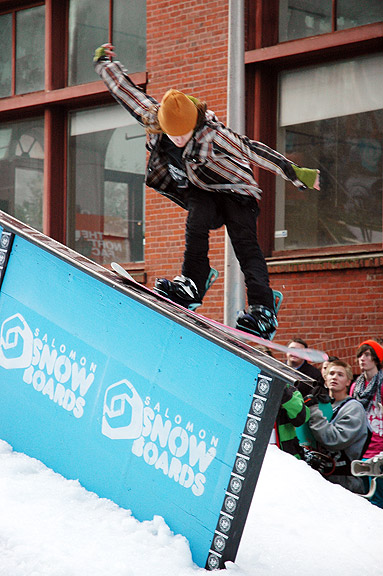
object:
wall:
[144, 0, 232, 330]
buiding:
[0, 0, 383, 381]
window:
[63, 92, 149, 266]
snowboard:
[110, 258, 329, 368]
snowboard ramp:
[0, 192, 329, 572]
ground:
[0, 440, 383, 576]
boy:
[93, 41, 320, 341]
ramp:
[0, 209, 327, 572]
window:
[244, 36, 383, 257]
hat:
[158, 88, 198, 136]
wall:
[262, 251, 383, 377]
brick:
[287, 303, 301, 310]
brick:
[300, 290, 312, 296]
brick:
[176, 49, 187, 56]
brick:
[151, 220, 162, 226]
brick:
[168, 258, 179, 263]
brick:
[167, 224, 179, 229]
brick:
[157, 259, 167, 264]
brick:
[297, 310, 306, 315]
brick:
[339, 326, 353, 332]